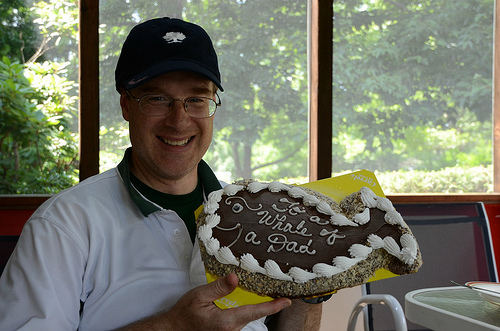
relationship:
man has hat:
[0, 15, 325, 331] [108, 11, 230, 98]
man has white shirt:
[0, 15, 325, 331] [20, 176, 204, 314]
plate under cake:
[192, 170, 414, 310] [215, 177, 407, 277]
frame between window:
[314, 0, 335, 178] [0, 1, 80, 194]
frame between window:
[314, 0, 335, 178] [99, 0, 309, 186]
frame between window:
[314, 0, 335, 178] [331, 1, 491, 194]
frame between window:
[81, 0, 102, 178] [0, 1, 80, 194]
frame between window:
[81, 0, 102, 178] [99, 0, 309, 186]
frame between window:
[81, 0, 102, 178] [331, 1, 491, 194]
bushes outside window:
[2, 6, 74, 177] [0, 1, 80, 194]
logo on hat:
[152, 22, 187, 52] [93, 9, 240, 104]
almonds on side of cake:
[197, 251, 424, 295] [190, 172, 425, 303]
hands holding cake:
[171, 263, 349, 329] [178, 158, 427, 316]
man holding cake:
[0, 15, 325, 331] [190, 172, 425, 303]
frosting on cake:
[215, 189, 406, 272] [190, 172, 425, 303]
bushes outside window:
[0, 0, 76, 192] [2, 2, 495, 198]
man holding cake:
[0, 15, 325, 331] [197, 178, 420, 296]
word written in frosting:
[256, 210, 314, 237] [206, 181, 416, 280]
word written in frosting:
[303, 209, 329, 224] [206, 181, 416, 280]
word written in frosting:
[315, 224, 345, 246] [206, 181, 416, 280]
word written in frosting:
[263, 231, 315, 256] [206, 181, 416, 280]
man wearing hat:
[0, 15, 325, 331] [127, 27, 223, 88]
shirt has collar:
[3, 143, 273, 329] [115, 142, 226, 219]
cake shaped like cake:
[197, 178, 420, 296] [197, 178, 420, 296]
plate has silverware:
[458, 274, 498, 304] [451, 277, 493, 296]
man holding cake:
[0, 15, 325, 331] [190, 155, 425, 311]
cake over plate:
[220, 156, 414, 283] [192, 170, 414, 310]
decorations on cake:
[220, 191, 344, 261] [190, 172, 425, 303]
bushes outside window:
[0, 0, 76, 192] [331, 1, 491, 194]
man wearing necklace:
[0, 4, 252, 329] [121, 173, 220, 219]